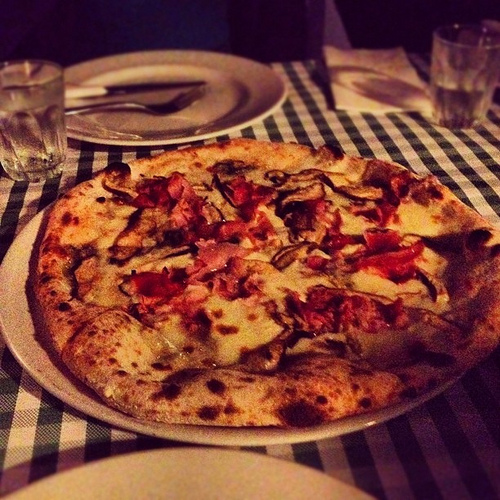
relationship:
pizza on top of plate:
[26, 136, 496, 429] [3, 195, 474, 446]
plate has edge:
[3, 195, 474, 446] [123, 429, 369, 446]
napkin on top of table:
[319, 35, 438, 123] [4, 62, 497, 321]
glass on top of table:
[426, 15, 497, 131] [4, 62, 497, 321]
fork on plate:
[60, 83, 208, 117] [31, 46, 287, 148]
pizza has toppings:
[26, 136, 496, 429] [132, 164, 210, 247]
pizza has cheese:
[26, 136, 496, 429] [142, 294, 286, 360]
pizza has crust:
[26, 136, 496, 429] [21, 174, 75, 360]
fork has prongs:
[60, 83, 208, 117] [178, 89, 205, 106]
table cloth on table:
[4, 46, 499, 322] [4, 62, 497, 321]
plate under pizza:
[3, 195, 474, 446] [26, 136, 496, 429]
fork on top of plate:
[60, 83, 208, 117] [3, 195, 474, 446]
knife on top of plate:
[64, 75, 211, 102] [3, 195, 474, 446]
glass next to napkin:
[426, 15, 497, 131] [319, 35, 438, 123]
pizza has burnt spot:
[26, 136, 496, 429] [270, 398, 332, 425]